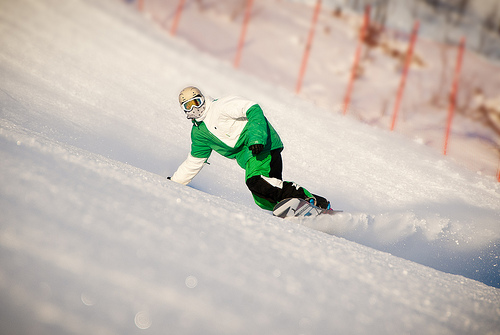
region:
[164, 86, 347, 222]
a man on icy slope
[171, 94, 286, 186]
man wearing white and green jacket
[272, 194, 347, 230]
gray and white ski board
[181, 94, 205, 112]
white goggles on man face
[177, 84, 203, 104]
man with gold helmet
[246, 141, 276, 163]
black glove on man hand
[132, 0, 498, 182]
orange poles on side of ice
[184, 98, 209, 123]
man with white face gear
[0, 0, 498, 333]
frozen ice slope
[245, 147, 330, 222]
man wearing black and white pant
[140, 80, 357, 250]
Man climbing the hill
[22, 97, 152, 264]
The hill is covered in snow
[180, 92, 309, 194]
Man wearing a snow suit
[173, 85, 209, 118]
Man wearing goggles and helmet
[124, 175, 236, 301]
The snow is glistening in the sun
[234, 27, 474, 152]
Orange fence in the background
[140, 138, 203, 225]
man touching the snow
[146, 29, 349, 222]
Man is snowboarding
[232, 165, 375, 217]
Man wearing snow pants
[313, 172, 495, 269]
The snow is blowing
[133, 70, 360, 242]
snowboarder on the slope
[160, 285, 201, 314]
patch of white snow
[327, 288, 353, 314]
patch of white snow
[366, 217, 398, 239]
patch of white snow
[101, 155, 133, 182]
patch of white snow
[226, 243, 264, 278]
patch of white snow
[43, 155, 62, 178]
patch of white snow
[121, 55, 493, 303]
a snowbaorder on the snow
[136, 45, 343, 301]
a snowboarding on the snow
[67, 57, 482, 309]
a man on asnowboard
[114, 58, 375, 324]
a man on the snow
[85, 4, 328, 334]
a man on the white snow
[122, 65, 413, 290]
a snowboarder wearing a helmte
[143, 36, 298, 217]
a man wearing a jacket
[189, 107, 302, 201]
a white and green jacket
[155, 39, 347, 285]
a snowboard weraing a white and green jacket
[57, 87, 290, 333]
a snow covered ground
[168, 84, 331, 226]
Snowboarder going down a hill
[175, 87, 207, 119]
The helmet is white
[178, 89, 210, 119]
The snowboarder is wearing goggles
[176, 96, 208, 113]
The goggles are white and yellow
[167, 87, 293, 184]
The snowboarder is wearing a jacket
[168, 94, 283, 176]
The jacket is green and white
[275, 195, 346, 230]
The snowboard has white writing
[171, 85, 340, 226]
The snowboarder is leaning on the snowboard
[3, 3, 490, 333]
The mountain is covered in snow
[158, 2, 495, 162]
The netting is orange